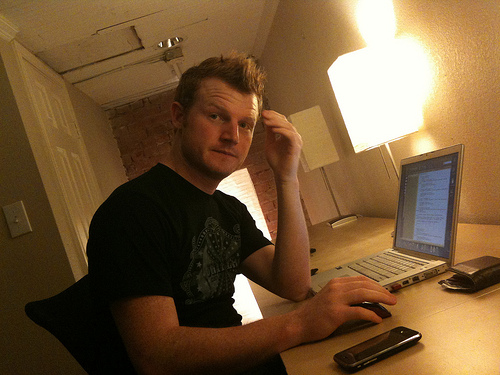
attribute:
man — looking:
[85, 50, 398, 374]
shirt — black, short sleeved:
[85, 163, 274, 327]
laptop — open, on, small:
[307, 143, 464, 297]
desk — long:
[244, 213, 500, 369]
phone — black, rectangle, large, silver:
[332, 324, 422, 372]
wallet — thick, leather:
[438, 254, 500, 294]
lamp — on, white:
[328, 44, 401, 182]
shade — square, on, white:
[325, 44, 421, 157]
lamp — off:
[286, 105, 359, 230]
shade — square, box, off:
[284, 101, 340, 175]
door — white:
[0, 40, 103, 282]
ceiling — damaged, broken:
[0, 1, 279, 109]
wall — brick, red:
[108, 87, 314, 243]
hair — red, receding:
[171, 50, 263, 137]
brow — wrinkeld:
[206, 100, 231, 114]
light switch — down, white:
[1, 200, 31, 240]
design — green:
[176, 213, 244, 308]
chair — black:
[24, 273, 131, 375]